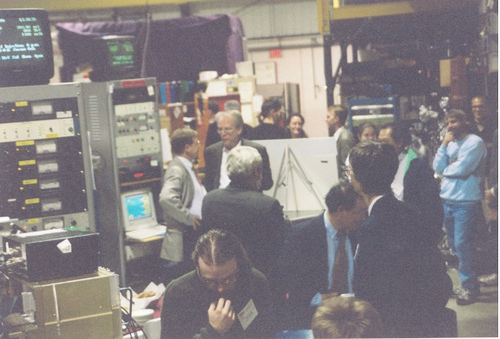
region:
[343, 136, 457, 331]
person standing inside building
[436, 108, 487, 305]
person standing inside building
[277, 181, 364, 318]
person standing inside building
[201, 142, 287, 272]
person standing inside building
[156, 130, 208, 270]
person standing inside building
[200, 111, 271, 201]
person standing inside building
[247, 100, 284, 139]
person standing inside building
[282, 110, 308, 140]
person standing inside building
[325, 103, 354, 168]
person standing inside building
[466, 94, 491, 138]
person standing inside building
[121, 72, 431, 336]
a group of people inside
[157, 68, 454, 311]
a group of people standing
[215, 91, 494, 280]
a group of poeple talking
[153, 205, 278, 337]
a man with a tag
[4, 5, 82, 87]
a tv that is turned on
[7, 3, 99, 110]
a black tv turned on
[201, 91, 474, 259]
a board on a stand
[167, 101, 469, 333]
men wearing ties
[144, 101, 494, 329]
men wearing suits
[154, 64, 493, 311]
men wearing suits and tie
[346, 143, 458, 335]
man is next to man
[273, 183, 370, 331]
man is next to man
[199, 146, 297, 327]
man is next to man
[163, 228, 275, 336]
man is next to man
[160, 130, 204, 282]
man is next to man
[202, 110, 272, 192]
man is next to man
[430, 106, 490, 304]
man is next to man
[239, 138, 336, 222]
white board is behind man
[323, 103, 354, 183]
man is next to man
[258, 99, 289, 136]
man is next to man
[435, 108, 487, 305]
a man wearing a blue sweater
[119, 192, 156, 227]
the screen of a computer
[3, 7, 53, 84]
the screen of a television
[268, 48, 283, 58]
a red exit sign above the door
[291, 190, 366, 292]
a man wearing a blue shirt and a red tie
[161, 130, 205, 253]
a man standing wearing a grey suit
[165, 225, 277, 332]
a man with glasses looking down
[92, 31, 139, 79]
a small television screen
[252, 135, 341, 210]
a white billboard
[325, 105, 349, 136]
a man wearing a white shirt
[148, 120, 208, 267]
person standing next to other people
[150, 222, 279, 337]
person standing next to other people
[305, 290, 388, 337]
head with brown hair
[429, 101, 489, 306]
person in blue jeans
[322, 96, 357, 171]
person in suit jacket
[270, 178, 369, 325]
person with blue shirt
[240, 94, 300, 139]
person with black hair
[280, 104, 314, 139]
woman with black hair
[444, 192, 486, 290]
pair of blue jeans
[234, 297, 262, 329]
white name tag on jacket